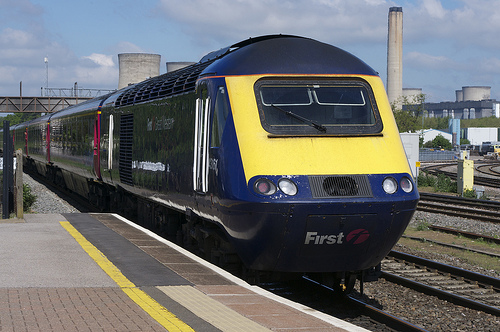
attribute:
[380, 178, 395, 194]
headlight — clear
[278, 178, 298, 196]
headlight — clear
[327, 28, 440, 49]
cloud — white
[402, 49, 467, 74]
cloud — white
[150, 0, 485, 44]
cloud — white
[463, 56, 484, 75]
cloud — white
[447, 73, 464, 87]
cloud — white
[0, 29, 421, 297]
train — black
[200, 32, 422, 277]
train front — blue, yellow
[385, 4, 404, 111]
smoke stack — tall, slim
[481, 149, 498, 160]
vehicle — yellow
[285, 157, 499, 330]
tracks — metal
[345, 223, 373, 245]
symbol — red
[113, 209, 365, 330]
stripe — white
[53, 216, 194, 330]
stripe — yellow, painted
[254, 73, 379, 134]
windshield — big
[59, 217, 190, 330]
painted line — yellow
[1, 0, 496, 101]
sky — daytime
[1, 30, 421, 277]
commuter train — large, blue, yellow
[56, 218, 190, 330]
line — yellow